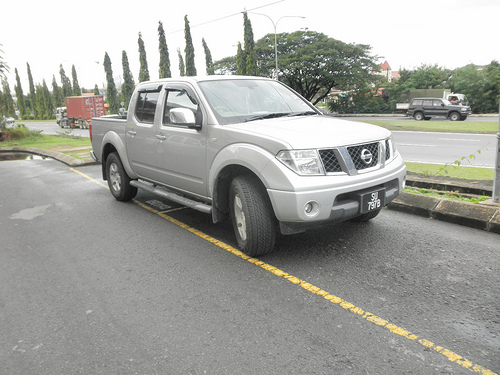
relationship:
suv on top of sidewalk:
[403, 90, 470, 125] [369, 105, 495, 127]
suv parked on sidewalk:
[403, 90, 470, 125] [369, 105, 495, 127]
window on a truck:
[134, 84, 158, 135] [73, 50, 450, 255]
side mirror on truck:
[168, 105, 200, 131] [88, 73, 408, 257]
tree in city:
[185, 14, 196, 83] [2, 1, 499, 371]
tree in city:
[240, 12, 252, 76] [2, 1, 499, 371]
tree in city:
[156, 17, 169, 79] [2, 1, 499, 371]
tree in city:
[136, 36, 146, 83] [2, 1, 499, 371]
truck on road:
[88, 73, 408, 257] [0, 148, 499, 374]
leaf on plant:
[292, 46, 301, 56] [252, 16, 390, 100]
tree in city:
[173, 48, 213, 70] [74, 32, 316, 128]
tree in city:
[165, 29, 227, 61] [76, 58, 318, 133]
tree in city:
[197, 31, 226, 69] [49, 58, 220, 102]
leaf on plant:
[287, 51, 313, 68] [256, 38, 381, 99]